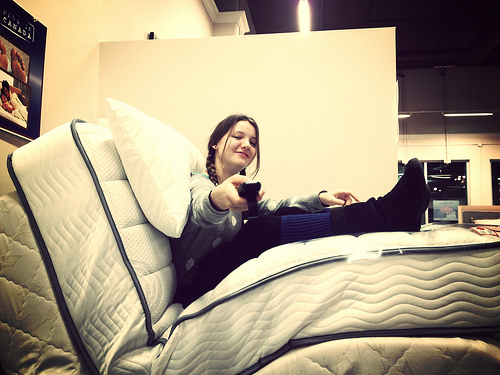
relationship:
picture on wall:
[0, 0, 48, 141] [13, 11, 155, 165]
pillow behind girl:
[123, 128, 178, 220] [151, 76, 355, 307]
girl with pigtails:
[151, 76, 355, 307] [175, 140, 231, 203]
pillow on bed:
[123, 128, 178, 220] [101, 194, 461, 372]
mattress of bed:
[326, 222, 471, 306] [101, 194, 461, 372]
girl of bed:
[151, 76, 355, 307] [101, 194, 461, 372]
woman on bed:
[163, 118, 309, 263] [101, 194, 461, 372]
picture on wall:
[48, 39, 443, 359] [13, 11, 155, 165]